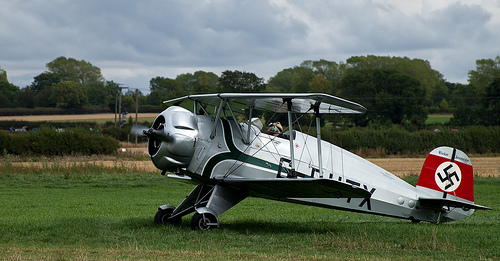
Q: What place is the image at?
A: It is at the field.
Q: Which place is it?
A: It is a field.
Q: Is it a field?
A: Yes, it is a field.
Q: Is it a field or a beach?
A: It is a field.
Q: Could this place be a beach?
A: No, it is a field.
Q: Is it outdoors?
A: Yes, it is outdoors.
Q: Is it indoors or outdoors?
A: It is outdoors.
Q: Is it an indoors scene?
A: No, it is outdoors.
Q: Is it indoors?
A: No, it is outdoors.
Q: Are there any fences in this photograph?
A: No, there are no fences.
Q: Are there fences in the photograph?
A: No, there are no fences.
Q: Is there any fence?
A: No, there are no fences.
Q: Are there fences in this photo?
A: No, there are no fences.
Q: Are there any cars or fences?
A: No, there are no fences or cars.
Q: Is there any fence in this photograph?
A: No, there are no fences.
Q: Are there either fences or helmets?
A: No, there are no fences or helmets.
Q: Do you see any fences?
A: No, there are no fences.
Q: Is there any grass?
A: Yes, there is grass.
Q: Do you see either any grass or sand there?
A: Yes, there is grass.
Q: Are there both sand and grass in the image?
A: Yes, there are both grass and sand.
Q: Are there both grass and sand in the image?
A: Yes, there are both grass and sand.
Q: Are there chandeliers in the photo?
A: No, there are no chandeliers.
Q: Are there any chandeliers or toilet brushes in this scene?
A: No, there are no chandeliers or toilet brushes.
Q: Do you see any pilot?
A: Yes, there is a pilot.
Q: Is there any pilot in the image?
A: Yes, there is a pilot.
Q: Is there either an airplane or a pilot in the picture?
A: Yes, there is a pilot.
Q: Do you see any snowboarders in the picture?
A: No, there are no snowboarders.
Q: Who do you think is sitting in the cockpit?
A: The pilot is sitting in the cockpit.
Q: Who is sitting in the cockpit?
A: The pilot is sitting in the cockpit.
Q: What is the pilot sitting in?
A: The pilot is sitting in the cockpit.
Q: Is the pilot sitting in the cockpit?
A: Yes, the pilot is sitting in the cockpit.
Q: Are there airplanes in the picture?
A: Yes, there is an airplane.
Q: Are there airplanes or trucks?
A: Yes, there is an airplane.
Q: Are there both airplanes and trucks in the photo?
A: No, there is an airplane but no trucks.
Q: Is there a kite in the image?
A: No, there are no kites.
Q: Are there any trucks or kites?
A: No, there are no kites or trucks.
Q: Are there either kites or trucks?
A: No, there are no kites or trucks.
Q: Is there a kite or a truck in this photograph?
A: No, there are no kites or trucks.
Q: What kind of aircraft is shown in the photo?
A: The aircraft is an airplane.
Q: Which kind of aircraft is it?
A: The aircraft is an airplane.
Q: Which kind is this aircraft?
A: This is an airplane.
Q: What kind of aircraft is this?
A: This is an airplane.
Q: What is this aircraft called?
A: This is an airplane.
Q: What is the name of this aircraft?
A: This is an airplane.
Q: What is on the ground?
A: The airplane is on the ground.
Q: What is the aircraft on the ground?
A: The aircraft is an airplane.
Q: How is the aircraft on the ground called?
A: The aircraft is an airplane.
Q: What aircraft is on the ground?
A: The aircraft is an airplane.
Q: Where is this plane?
A: The plane is on the ground.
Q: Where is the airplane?
A: The plane is on the ground.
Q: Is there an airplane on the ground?
A: Yes, there is an airplane on the ground.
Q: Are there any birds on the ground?
A: No, there is an airplane on the ground.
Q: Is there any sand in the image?
A: Yes, there is sand.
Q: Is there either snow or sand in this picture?
A: Yes, there is sand.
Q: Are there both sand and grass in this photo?
A: Yes, there are both sand and grass.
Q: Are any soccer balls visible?
A: No, there are no soccer balls.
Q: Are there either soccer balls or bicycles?
A: No, there are no soccer balls or bicycles.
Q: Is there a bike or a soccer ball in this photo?
A: No, there are no soccer balls or bikes.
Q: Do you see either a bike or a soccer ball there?
A: No, there are no soccer balls or bikes.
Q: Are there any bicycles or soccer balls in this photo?
A: No, there are no soccer balls or bicycles.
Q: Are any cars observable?
A: No, there are no cars.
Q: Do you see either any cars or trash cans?
A: No, there are no cars or trash cans.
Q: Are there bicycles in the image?
A: No, there are no bicycles.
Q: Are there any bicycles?
A: No, there are no bicycles.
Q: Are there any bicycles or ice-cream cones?
A: No, there are no bicycles or ice-cream cones.